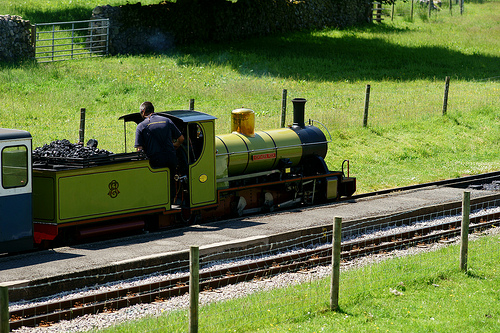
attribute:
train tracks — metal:
[9, 168, 499, 332]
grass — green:
[14, 25, 497, 180]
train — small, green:
[3, 90, 358, 253]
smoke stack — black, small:
[291, 95, 310, 125]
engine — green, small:
[130, 89, 358, 231]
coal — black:
[32, 135, 107, 164]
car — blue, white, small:
[0, 125, 36, 251]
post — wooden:
[362, 82, 374, 131]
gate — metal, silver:
[34, 15, 110, 64]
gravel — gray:
[49, 294, 241, 330]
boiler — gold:
[228, 107, 259, 136]